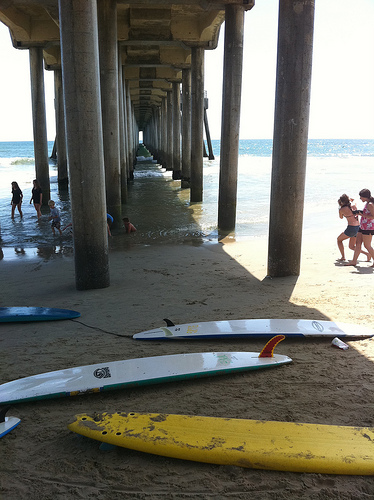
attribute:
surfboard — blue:
[2, 299, 93, 333]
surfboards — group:
[4, 284, 373, 484]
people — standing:
[5, 172, 66, 243]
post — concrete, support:
[56, 1, 125, 297]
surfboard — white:
[4, 341, 309, 406]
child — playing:
[37, 197, 69, 243]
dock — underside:
[2, 0, 316, 298]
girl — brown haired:
[353, 183, 373, 269]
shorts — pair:
[339, 220, 365, 239]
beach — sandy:
[2, 152, 373, 498]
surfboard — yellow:
[66, 404, 373, 481]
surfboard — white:
[132, 311, 372, 357]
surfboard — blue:
[2, 296, 86, 332]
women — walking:
[333, 182, 373, 276]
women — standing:
[7, 177, 47, 232]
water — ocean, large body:
[2, 141, 373, 258]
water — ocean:
[7, 139, 364, 271]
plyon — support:
[262, 10, 323, 275]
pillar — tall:
[268, 1, 326, 283]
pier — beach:
[3, 0, 323, 297]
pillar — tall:
[56, 0, 112, 292]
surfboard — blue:
[1, 302, 84, 325]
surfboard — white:
[0, 333, 297, 407]